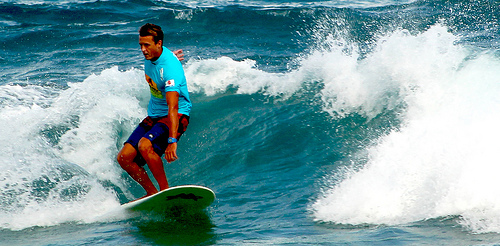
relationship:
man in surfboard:
[116, 23, 193, 203] [116, 181, 222, 214]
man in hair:
[116, 23, 193, 203] [138, 21, 164, 45]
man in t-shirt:
[111, 17, 196, 202] [139, 42, 195, 120]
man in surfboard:
[116, 23, 193, 203] [93, 157, 238, 219]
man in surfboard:
[116, 23, 193, 203] [121, 184, 213, 216]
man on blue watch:
[116, 23, 193, 203] [166, 133, 177, 142]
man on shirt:
[116, 23, 193, 203] [143, 47, 200, 127]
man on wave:
[116, 23, 193, 203] [304, 22, 499, 231]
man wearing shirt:
[116, 23, 193, 203] [136, 63, 191, 113]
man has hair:
[116, 23, 193, 203] [135, 21, 166, 45]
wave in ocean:
[361, 65, 470, 170] [27, 15, 459, 218]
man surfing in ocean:
[116, 23, 193, 203] [4, 2, 483, 242]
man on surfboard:
[116, 23, 193, 203] [114, 184, 220, 217]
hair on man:
[134, 24, 164, 42] [111, 17, 196, 202]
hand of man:
[162, 136, 182, 166] [116, 13, 195, 186]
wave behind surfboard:
[0, 21, 500, 235] [118, 176, 222, 219]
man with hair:
[116, 23, 193, 203] [135, 20, 165, 50]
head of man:
[135, 16, 165, 64] [116, 23, 193, 203]